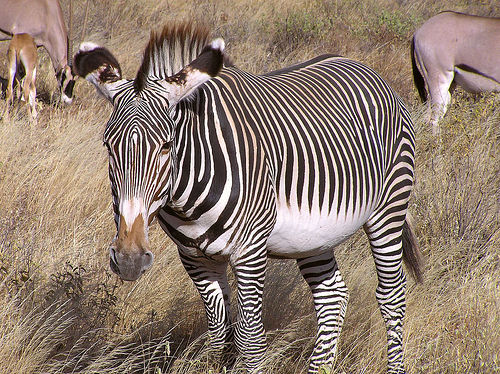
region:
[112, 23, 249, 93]
hairs in zebra's mane is sticking straight up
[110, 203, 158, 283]
zebra has a brown spot in the front of its face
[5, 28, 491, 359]
zebra standing in very high grass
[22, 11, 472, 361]
grass is brown and dry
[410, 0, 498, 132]
animal that is not a zebra in upper right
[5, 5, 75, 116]
another kind of animal that is not a zebra in upper left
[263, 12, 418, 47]
patch of a green plant behind the zebra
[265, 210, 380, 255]
the belly of the zebra is white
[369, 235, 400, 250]
black strip on zebra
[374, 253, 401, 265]
black strip on zebra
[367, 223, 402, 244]
black strip on zebra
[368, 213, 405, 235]
black strip on zebra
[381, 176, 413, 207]
black strip on zebra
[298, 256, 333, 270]
black strip on zebra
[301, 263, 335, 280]
black strip on zebra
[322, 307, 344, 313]
black strip on zebra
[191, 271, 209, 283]
black strip on zebra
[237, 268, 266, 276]
black strip on zebra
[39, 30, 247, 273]
head of a zebra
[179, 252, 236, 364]
leg of a zebra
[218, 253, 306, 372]
leg of a zebra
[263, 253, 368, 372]
leg of a zebra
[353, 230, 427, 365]
leg of a zebra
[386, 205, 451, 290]
tail of a zebra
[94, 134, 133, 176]
eye of a zebra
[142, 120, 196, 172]
eye of a zebra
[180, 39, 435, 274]
body of a zebra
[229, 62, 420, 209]
skin of a zebra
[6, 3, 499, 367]
Wild animals standing in the forest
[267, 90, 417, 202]
Black and white color stripes of the zebra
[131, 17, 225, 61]
Black and white color manes of the zebra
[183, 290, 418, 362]
Legs of the zebra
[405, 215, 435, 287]
Tail of the zebra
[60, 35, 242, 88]
Large upright ears of the zebra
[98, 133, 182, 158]
Eyes of the zebra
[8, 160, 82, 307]
Brown color grass in the forest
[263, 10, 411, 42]
Small plant with green leaves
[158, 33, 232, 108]
the ear of a zebra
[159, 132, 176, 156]
the eye of a zebra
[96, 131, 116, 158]
the eye of a zebra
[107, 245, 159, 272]
the nose of a zebra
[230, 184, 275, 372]
the front leg of a zebra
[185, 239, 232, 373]
the front leg of a zebra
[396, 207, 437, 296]
the tail of a zebra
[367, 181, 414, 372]
the hind leg of a zebra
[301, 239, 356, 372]
the hind leg of a zebra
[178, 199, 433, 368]
four legs of zebra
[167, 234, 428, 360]
four legs of zebra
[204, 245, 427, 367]
four legs of zebra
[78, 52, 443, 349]
The zebra is black and white.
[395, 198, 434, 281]
The tail of the zebra.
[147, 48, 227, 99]
The ear of the zebra.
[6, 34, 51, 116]
A small animal in the background.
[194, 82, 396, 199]
the zebra has stripes.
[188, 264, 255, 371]
Front legs the zebra.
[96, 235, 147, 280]
Nose of the zebra.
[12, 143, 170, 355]
The grass is tall and dry.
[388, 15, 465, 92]
The back end of the animal.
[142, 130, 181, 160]
The eye of the zebra.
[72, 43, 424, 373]
Black and white zebra